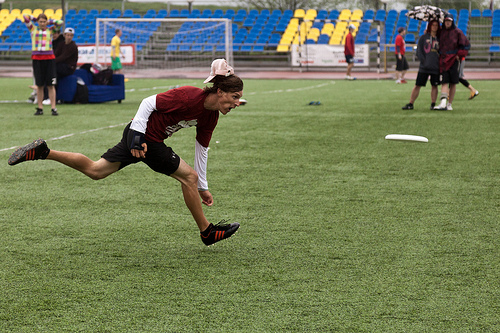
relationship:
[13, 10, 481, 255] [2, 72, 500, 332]
people on field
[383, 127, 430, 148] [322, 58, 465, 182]
frisbee in air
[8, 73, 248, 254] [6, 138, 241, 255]
man wearing shoes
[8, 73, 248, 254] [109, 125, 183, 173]
man wearing shorts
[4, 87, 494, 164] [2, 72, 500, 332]
lines on field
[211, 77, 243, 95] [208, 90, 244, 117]
cap on head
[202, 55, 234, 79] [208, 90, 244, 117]
hat on head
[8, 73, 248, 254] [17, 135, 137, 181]
man lifting h leg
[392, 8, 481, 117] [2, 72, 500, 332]
people walking on field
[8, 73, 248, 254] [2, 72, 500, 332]
man running on field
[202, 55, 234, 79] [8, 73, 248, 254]
hat falling off man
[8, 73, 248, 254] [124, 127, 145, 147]
man wearing glove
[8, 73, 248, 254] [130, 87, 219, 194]
man wearing shirt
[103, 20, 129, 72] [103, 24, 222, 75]
man standing in net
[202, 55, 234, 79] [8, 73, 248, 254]
hat on man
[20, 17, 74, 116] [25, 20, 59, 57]
woman wearing sweater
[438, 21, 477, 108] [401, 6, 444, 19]
man holding umbrella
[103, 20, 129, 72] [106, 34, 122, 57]
man in shirt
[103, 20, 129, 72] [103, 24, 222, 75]
man standing by net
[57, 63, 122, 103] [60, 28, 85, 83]
sofa behind man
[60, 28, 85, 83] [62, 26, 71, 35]
man in hat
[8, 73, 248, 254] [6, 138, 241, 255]
man has shoes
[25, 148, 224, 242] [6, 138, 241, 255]
stripes on shoes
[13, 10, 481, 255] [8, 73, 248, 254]
people watching man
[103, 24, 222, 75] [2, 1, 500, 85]
net in background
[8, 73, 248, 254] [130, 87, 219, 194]
man has shirt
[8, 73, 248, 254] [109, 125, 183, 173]
man has shorts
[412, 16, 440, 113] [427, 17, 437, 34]
man has hood